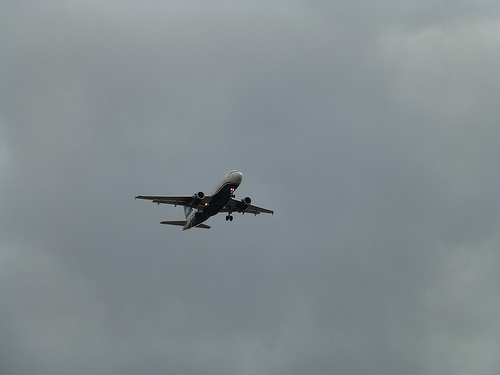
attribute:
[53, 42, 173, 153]
clouds — white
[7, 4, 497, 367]
sky — blue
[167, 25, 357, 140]
clouds — white